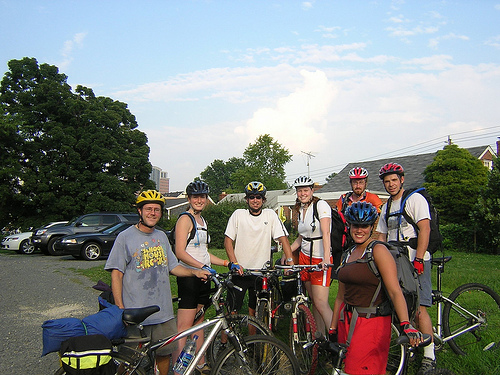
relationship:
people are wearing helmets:
[102, 188, 213, 375] [124, 164, 421, 231]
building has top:
[327, 141, 499, 203] [341, 141, 494, 174]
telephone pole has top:
[301, 143, 317, 176] [297, 147, 318, 159]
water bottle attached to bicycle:
[175, 334, 198, 373] [105, 302, 274, 374]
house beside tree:
[327, 141, 499, 203] [425, 142, 484, 247]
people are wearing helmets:
[117, 169, 441, 329] [124, 164, 421, 231]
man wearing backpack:
[382, 168, 443, 285] [398, 188, 442, 252]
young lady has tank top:
[337, 207, 408, 314] [337, 249, 394, 313]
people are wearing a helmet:
[102, 188, 213, 375] [185, 170, 412, 198]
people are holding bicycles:
[117, 169, 441, 329] [52, 251, 491, 373]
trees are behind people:
[6, 55, 489, 181] [117, 169, 441, 329]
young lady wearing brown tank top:
[327, 199, 422, 375] [337, 249, 394, 313]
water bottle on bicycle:
[175, 334, 198, 373] [92, 270, 280, 375]